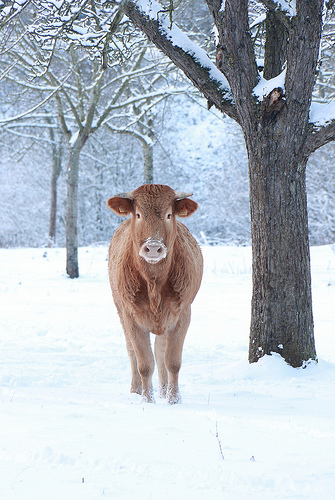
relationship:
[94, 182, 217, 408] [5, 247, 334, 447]
cow in snow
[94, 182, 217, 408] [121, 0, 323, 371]
cow near tree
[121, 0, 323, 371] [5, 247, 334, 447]
tree covered in snow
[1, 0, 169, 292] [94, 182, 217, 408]
trees behind cow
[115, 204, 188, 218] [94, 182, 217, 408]
tag on cow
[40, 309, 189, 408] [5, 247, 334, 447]
tracks in snow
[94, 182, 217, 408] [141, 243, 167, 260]
cow has nose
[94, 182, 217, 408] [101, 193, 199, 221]
cow has ears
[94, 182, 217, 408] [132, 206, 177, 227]
cow has eyes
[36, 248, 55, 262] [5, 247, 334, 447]
twig in snow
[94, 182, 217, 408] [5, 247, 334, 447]
cow standing in snow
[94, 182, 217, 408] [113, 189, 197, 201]
cow has horns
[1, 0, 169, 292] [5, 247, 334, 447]
trees covered in snow